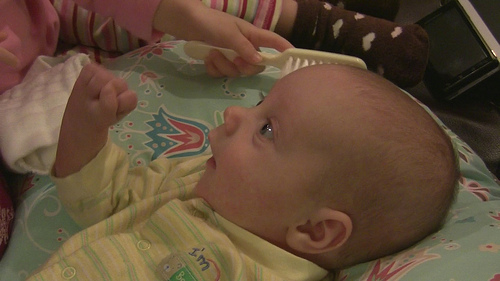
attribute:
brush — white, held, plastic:
[185, 39, 366, 76]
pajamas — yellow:
[26, 140, 331, 281]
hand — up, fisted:
[74, 61, 137, 129]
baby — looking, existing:
[27, 63, 460, 280]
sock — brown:
[289, 2, 427, 89]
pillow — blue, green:
[1, 39, 498, 281]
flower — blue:
[146, 106, 213, 162]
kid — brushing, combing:
[0, 2, 432, 94]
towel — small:
[0, 51, 94, 177]